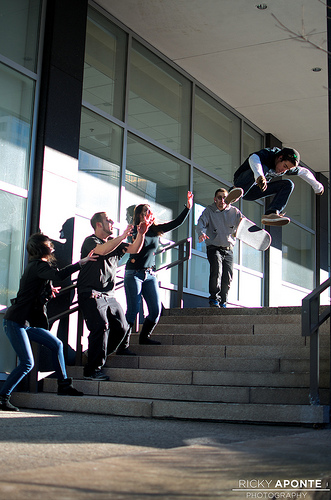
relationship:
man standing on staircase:
[204, 186, 236, 307] [148, 306, 310, 419]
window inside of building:
[131, 39, 194, 162] [24, 8, 314, 308]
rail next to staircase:
[172, 242, 198, 259] [148, 306, 310, 419]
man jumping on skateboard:
[218, 138, 326, 225] [239, 220, 272, 252]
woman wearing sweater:
[128, 205, 170, 343] [146, 240, 157, 267]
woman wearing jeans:
[1, 231, 73, 399] [8, 326, 33, 364]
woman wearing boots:
[1, 231, 73, 399] [55, 378, 93, 397]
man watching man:
[83, 213, 133, 383] [218, 138, 326, 225]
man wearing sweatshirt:
[204, 186, 236, 307] [207, 211, 234, 246]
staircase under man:
[148, 306, 310, 419] [218, 138, 326, 225]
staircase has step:
[148, 306, 310, 419] [104, 383, 311, 404]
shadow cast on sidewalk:
[15, 419, 175, 446] [11, 418, 323, 499]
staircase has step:
[148, 306, 310, 419] [169, 308, 305, 315]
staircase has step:
[148, 306, 310, 419] [161, 327, 303, 336]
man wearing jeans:
[83, 213, 133, 383] [88, 297, 121, 352]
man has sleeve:
[218, 138, 326, 225] [250, 156, 262, 180]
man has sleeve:
[218, 138, 326, 225] [300, 170, 326, 191]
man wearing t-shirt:
[218, 138, 326, 225] [261, 153, 275, 167]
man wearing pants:
[204, 186, 236, 307] [211, 255, 231, 297]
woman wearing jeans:
[128, 205, 170, 343] [8, 326, 33, 364]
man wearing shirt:
[78, 213, 152, 381] [90, 266, 113, 290]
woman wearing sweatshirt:
[1, 231, 73, 399] [22, 268, 43, 318]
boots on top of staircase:
[55, 378, 93, 397] [148, 306, 310, 419]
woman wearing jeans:
[128, 205, 170, 343] [125, 274, 161, 321]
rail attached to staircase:
[303, 299, 324, 400] [148, 306, 310, 419]